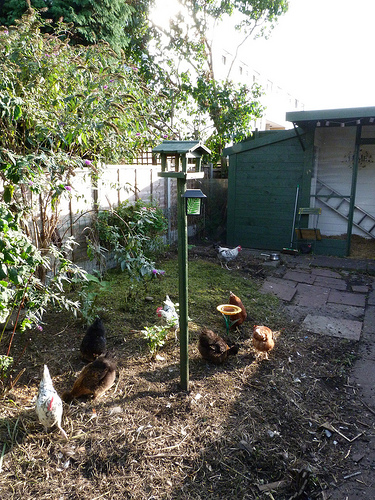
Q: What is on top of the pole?
A: Birdhouse.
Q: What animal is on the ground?
A: Chicken.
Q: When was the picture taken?
A: Daytime.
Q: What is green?
A: The house.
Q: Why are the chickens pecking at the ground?
A: Looking for worms.